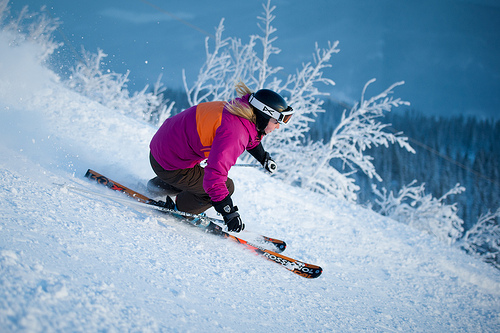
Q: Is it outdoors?
A: Yes, it is outdoors.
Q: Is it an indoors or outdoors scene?
A: It is outdoors.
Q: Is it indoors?
A: No, it is outdoors.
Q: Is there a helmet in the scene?
A: Yes, there is a helmet.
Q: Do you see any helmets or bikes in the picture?
A: Yes, there is a helmet.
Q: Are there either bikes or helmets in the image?
A: Yes, there is a helmet.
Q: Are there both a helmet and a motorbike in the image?
A: No, there is a helmet but no motorcycles.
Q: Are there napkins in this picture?
A: No, there are no napkins.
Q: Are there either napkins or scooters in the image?
A: No, there are no napkins or scooters.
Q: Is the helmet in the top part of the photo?
A: Yes, the helmet is in the top of the image.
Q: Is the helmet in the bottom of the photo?
A: No, the helmet is in the top of the image.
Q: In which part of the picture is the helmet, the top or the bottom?
A: The helmet is in the top of the image.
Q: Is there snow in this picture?
A: Yes, there is snow.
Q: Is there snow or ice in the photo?
A: Yes, there is snow.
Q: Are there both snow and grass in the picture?
A: No, there is snow but no grass.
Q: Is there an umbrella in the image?
A: No, there are no umbrellas.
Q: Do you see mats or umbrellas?
A: No, there are no umbrellas or mats.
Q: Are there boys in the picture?
A: No, there are no boys.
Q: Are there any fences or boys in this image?
A: No, there are no boys or fences.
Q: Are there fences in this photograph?
A: No, there are no fences.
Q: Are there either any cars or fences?
A: No, there are no fences or cars.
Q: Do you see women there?
A: Yes, there is a woman.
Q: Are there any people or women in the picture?
A: Yes, there is a woman.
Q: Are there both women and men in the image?
A: No, there is a woman but no men.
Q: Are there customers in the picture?
A: No, there are no customers.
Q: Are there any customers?
A: No, there are no customers.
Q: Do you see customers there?
A: No, there are no customers.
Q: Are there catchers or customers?
A: No, there are no customers or catchers.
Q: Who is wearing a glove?
A: The woman is wearing a glove.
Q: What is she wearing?
A: The woman is wearing a glove.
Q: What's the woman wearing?
A: The woman is wearing a glove.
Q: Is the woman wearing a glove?
A: Yes, the woman is wearing a glove.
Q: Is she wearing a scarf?
A: No, the woman is wearing a glove.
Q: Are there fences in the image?
A: No, there are no fences.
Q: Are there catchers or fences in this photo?
A: No, there are no fences or catchers.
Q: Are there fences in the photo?
A: No, there are no fences.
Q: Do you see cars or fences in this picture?
A: No, there are no fences or cars.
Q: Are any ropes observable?
A: No, there are no ropes.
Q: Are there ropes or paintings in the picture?
A: No, there are no ropes or paintings.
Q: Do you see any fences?
A: No, there are no fences.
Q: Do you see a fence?
A: No, there are no fences.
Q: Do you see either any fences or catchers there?
A: No, there are no fences or catchers.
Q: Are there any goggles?
A: Yes, there are goggles.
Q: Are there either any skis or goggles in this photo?
A: Yes, there are goggles.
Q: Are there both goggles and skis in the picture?
A: Yes, there are both goggles and skis.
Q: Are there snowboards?
A: No, there are no snowboards.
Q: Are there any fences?
A: No, there are no fences.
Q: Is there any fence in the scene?
A: No, there are no fences.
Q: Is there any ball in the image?
A: No, there are no balls.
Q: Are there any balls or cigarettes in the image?
A: No, there are no balls or cigarettes.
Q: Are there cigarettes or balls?
A: No, there are no balls or cigarettes.